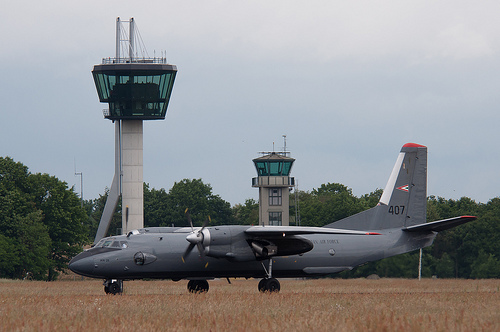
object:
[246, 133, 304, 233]
tower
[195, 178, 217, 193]
tree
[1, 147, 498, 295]
leaves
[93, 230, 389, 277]
plane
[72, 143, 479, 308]
grey airplane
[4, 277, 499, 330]
runway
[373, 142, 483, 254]
tail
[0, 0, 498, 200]
overcast sky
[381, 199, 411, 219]
numbers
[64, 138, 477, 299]
plane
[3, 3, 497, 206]
sky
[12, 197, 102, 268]
leaves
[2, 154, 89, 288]
tree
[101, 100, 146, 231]
tower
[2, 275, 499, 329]
brown grass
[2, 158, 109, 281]
trees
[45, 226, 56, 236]
leaves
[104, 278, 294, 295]
wheels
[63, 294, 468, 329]
ground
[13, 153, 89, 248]
trees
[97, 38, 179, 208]
towers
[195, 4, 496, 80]
clouds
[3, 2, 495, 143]
sky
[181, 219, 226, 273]
propeller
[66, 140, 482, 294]
airplane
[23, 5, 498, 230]
sky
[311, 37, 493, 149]
clouds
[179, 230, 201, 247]
propeller nose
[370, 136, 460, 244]
tail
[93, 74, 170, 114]
windows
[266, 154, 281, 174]
windows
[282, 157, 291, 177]
windows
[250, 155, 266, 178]
windows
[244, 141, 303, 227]
tower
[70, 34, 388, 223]
towers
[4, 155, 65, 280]
trees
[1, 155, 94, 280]
leaves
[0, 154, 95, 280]
tree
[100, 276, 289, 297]
three wheels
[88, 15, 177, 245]
tower